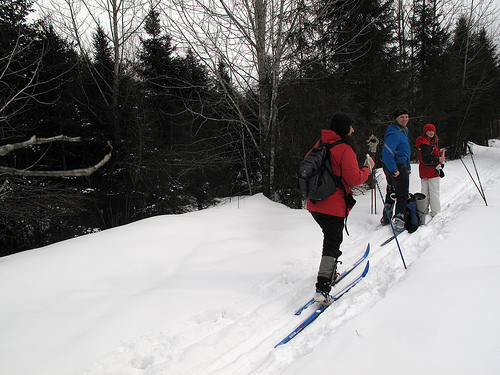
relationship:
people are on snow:
[298, 109, 446, 309] [1, 140, 500, 375]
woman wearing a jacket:
[297, 107, 370, 317] [303, 129, 370, 219]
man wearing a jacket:
[380, 107, 408, 236] [380, 123, 410, 175]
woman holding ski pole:
[297, 107, 370, 317] [363, 156, 413, 273]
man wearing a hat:
[380, 107, 408, 236] [390, 104, 412, 119]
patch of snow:
[359, 330, 426, 371] [1, 140, 500, 375]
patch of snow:
[186, 292, 246, 337] [1, 140, 500, 375]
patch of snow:
[389, 265, 420, 325] [1, 140, 500, 375]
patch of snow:
[93, 319, 141, 347] [1, 140, 500, 375]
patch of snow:
[50, 261, 90, 301] [1, 140, 500, 375]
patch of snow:
[211, 278, 244, 318] [1, 140, 500, 375]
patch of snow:
[77, 302, 193, 351] [1, 140, 500, 375]